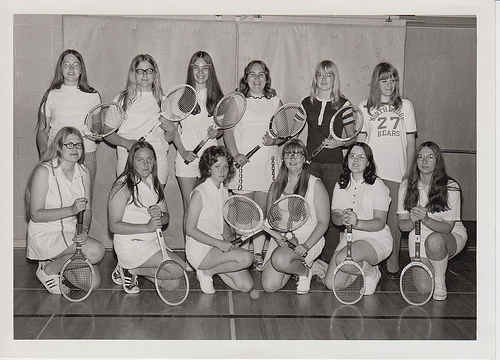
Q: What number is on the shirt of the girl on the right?
A: 27.